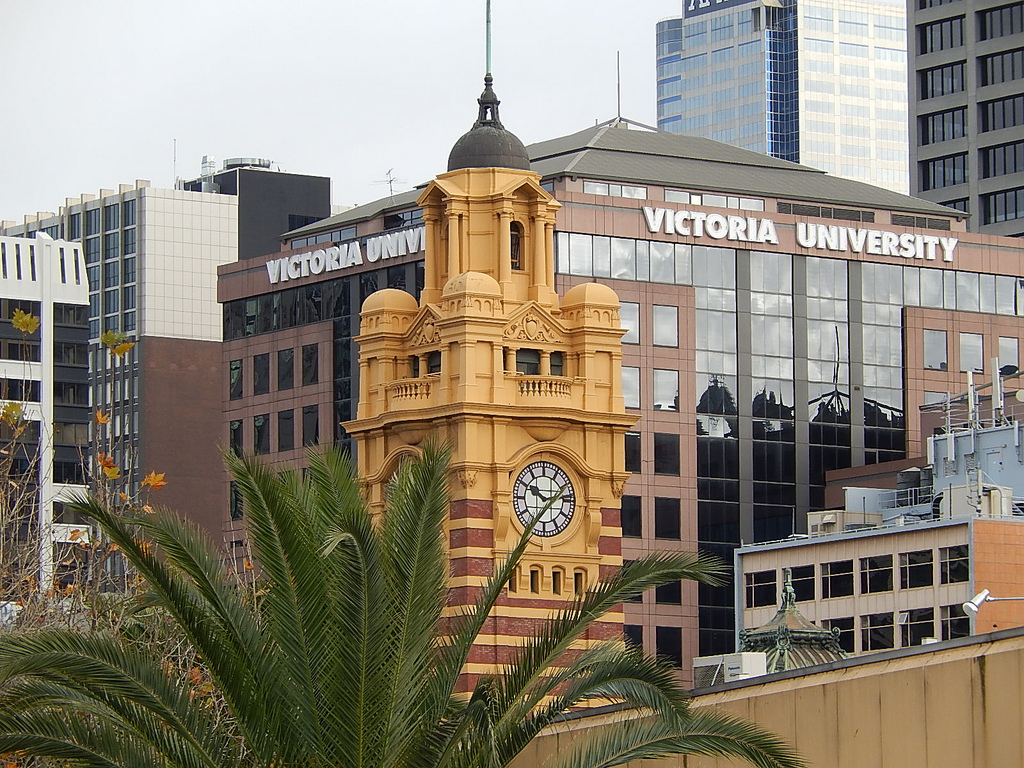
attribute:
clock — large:
[498, 454, 578, 554]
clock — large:
[504, 451, 587, 565]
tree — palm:
[1, 451, 769, 766]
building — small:
[450, 629, 1023, 766]